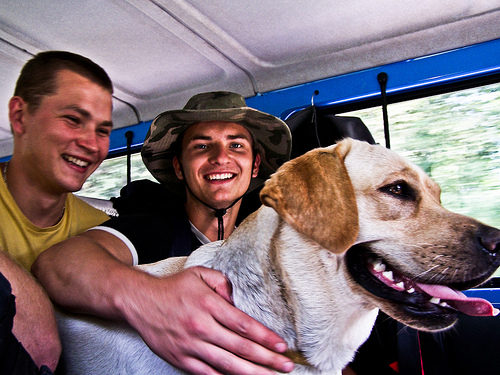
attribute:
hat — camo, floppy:
[145, 90, 289, 184]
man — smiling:
[35, 100, 340, 374]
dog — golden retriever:
[50, 139, 500, 362]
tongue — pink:
[421, 280, 498, 327]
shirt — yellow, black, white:
[1, 166, 110, 261]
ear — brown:
[261, 144, 368, 254]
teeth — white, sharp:
[373, 260, 433, 292]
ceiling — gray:
[1, 1, 500, 131]